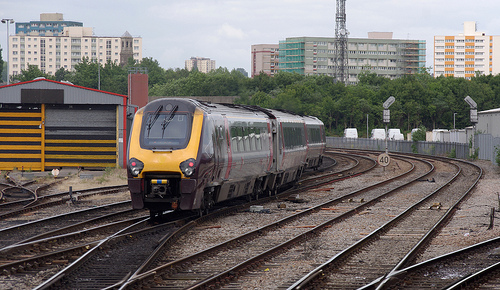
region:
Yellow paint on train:
[128, 98, 200, 175]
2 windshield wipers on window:
[147, 100, 182, 134]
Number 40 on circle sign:
[374, 150, 394, 167]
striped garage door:
[44, 107, 117, 170]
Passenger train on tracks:
[119, 96, 329, 211]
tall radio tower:
[333, 1, 354, 86]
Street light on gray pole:
[1, 14, 16, 86]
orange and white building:
[427, 25, 496, 79]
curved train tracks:
[328, 138, 483, 193]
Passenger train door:
[215, 115, 238, 184]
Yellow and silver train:
[121, 102, 339, 215]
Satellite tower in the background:
[315, 1, 356, 89]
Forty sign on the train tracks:
[370, 147, 395, 172]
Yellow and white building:
[423, 15, 498, 84]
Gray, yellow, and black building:
[1, 65, 128, 175]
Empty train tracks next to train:
[232, 136, 486, 288]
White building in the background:
[4, 15, 146, 85]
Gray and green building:
[256, 29, 427, 87]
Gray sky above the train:
[25, 10, 497, 31]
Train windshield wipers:
[140, 102, 181, 134]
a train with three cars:
[123, 100, 342, 223]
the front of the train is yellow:
[127, 98, 202, 204]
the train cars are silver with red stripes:
[227, 107, 325, 201]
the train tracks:
[6, 206, 160, 288]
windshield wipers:
[147, 103, 187, 133]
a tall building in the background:
[275, 20, 434, 92]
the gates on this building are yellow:
[6, 98, 119, 168]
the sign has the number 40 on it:
[378, 151, 394, 176]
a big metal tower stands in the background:
[328, 2, 366, 89]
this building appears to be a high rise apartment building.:
[423, 22, 495, 88]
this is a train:
[126, 109, 306, 172]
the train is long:
[137, 108, 299, 163]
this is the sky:
[150, 3, 263, 38]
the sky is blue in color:
[89, 0, 126, 20]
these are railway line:
[110, 230, 250, 288]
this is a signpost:
[375, 152, 391, 173]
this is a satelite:
[333, 4, 348, 72]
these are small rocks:
[335, 227, 355, 234]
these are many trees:
[332, 86, 366, 106]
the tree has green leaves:
[322, 81, 338, 97]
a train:
[108, 62, 370, 227]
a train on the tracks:
[121, 75, 389, 227]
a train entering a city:
[22, 11, 489, 227]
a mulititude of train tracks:
[35, 102, 495, 289]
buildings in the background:
[12, 14, 495, 154]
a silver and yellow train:
[101, 64, 389, 227]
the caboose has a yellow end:
[130, 92, 288, 229]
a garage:
[6, 71, 146, 225]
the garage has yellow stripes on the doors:
[7, 64, 159, 236]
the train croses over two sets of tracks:
[114, 69, 444, 224]